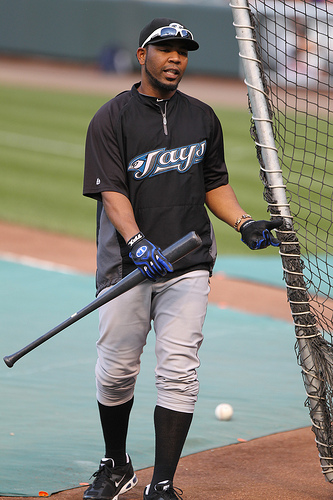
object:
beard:
[145, 64, 183, 91]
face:
[145, 45, 189, 92]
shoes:
[81, 452, 138, 499]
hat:
[139, 22, 200, 52]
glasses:
[140, 22, 193, 48]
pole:
[229, 0, 333, 487]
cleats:
[83, 451, 138, 499]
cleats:
[142, 480, 183, 500]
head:
[135, 16, 188, 92]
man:
[82, 18, 283, 500]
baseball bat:
[2, 230, 202, 367]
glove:
[126, 231, 174, 282]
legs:
[143, 270, 211, 500]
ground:
[182, 453, 228, 497]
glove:
[240, 220, 282, 251]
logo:
[127, 139, 206, 181]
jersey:
[82, 79, 229, 296]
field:
[0, 63, 333, 500]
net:
[227, 0, 333, 487]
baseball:
[215, 403, 234, 422]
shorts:
[94, 268, 210, 414]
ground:
[271, 436, 301, 480]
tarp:
[0, 258, 331, 500]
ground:
[0, 52, 63, 298]